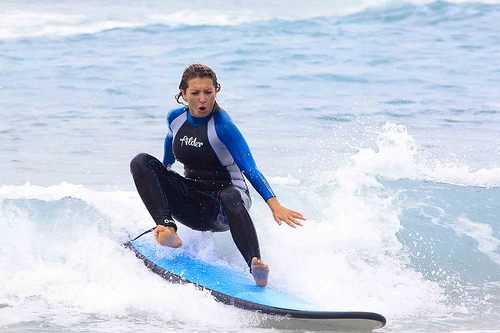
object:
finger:
[281, 216, 297, 229]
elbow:
[234, 155, 257, 168]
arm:
[218, 120, 276, 199]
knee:
[129, 153, 159, 176]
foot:
[250, 256, 270, 288]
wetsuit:
[129, 106, 277, 273]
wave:
[0, 97, 499, 333]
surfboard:
[119, 226, 386, 332]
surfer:
[129, 62, 308, 288]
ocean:
[0, 0, 497, 333]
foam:
[417, 203, 500, 266]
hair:
[173, 63, 221, 113]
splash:
[342, 119, 500, 191]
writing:
[179, 134, 204, 148]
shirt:
[163, 103, 277, 204]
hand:
[271, 202, 307, 229]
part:
[350, 120, 373, 136]